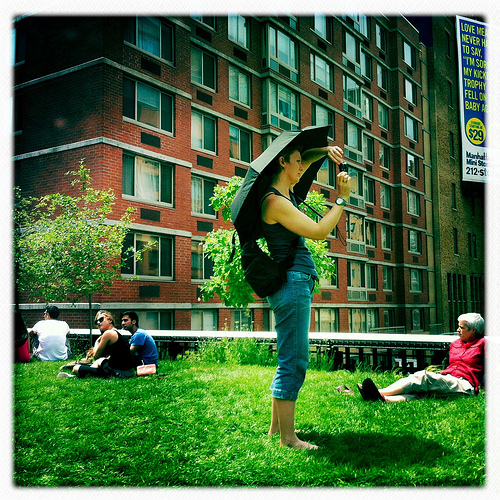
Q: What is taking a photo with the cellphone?
A: The woman is taking the photo.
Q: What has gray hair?
A: The man.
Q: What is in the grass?
A: Two trees.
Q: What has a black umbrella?
A: The woman.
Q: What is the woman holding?
A: Phone.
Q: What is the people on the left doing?
A: Sitting.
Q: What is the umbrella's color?
A: Black.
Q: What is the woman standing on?
A: Grass.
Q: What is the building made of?
A: Brick.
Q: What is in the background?
A: Building.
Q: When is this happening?
A: During the day time.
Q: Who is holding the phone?
A: A woman.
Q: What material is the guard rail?
A: Metal rail.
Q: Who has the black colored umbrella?
A: Lady with blue jeans.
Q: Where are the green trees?
A: Front of building.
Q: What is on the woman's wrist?
A: Watch.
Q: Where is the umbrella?
A: On the woman's head.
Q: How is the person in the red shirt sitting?
A: Cross-legged.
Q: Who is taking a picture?
A: The woman with the umbrella.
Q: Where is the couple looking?
A: To their left.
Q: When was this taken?
A: Daytime.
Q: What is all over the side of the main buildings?
A: Windows.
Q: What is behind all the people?
A: Building.